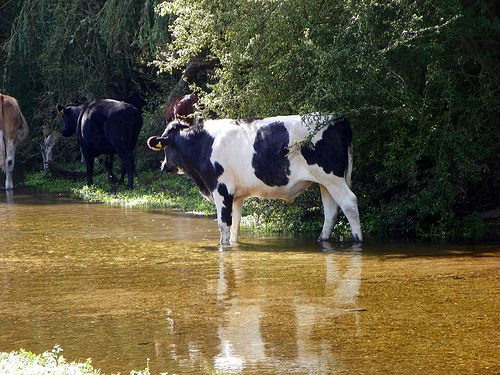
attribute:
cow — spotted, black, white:
[148, 109, 364, 248]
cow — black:
[50, 98, 142, 191]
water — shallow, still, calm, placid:
[2, 184, 499, 373]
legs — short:
[294, 159, 371, 249]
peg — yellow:
[152, 135, 167, 148]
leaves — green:
[241, 31, 436, 77]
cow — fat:
[40, 92, 154, 197]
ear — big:
[138, 130, 168, 155]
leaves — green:
[222, 13, 459, 103]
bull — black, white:
[124, 105, 365, 262]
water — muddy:
[2, 242, 445, 369]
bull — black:
[43, 84, 153, 195]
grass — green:
[46, 152, 160, 195]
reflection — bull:
[201, 287, 333, 371]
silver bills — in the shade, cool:
[1, 77, 158, 212]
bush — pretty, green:
[190, 11, 452, 113]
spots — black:
[244, 119, 356, 185]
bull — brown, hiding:
[117, 90, 203, 125]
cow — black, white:
[153, 115, 400, 265]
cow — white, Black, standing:
[138, 101, 366, 259]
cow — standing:
[137, 90, 349, 251]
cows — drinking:
[9, 90, 245, 224]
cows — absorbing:
[24, 74, 374, 269]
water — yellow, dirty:
[12, 238, 369, 365]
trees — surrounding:
[15, 20, 484, 125]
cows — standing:
[37, 95, 387, 232]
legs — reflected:
[192, 185, 371, 250]